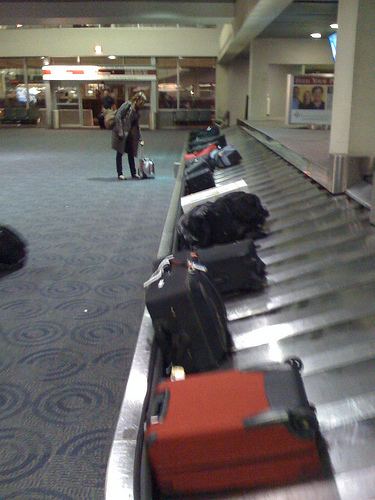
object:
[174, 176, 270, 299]
bunch of luggage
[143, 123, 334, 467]
row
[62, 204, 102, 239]
carpet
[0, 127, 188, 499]
floor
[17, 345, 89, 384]
circular design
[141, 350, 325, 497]
bag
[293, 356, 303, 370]
wheels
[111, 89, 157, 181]
woman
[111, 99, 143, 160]
coat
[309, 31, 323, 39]
light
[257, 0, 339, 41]
ceiling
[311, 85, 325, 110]
people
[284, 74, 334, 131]
advertisement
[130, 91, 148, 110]
hair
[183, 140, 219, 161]
luggage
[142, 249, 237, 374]
luggage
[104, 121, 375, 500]
baggage carousel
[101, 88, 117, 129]
man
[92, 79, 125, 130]
entryway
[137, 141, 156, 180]
luggage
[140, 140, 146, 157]
handle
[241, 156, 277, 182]
belt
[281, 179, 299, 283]
metal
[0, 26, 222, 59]
wall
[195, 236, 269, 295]
suitcase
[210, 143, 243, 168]
suitcase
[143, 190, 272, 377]
three suitcases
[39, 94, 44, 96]
shops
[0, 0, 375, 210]
airport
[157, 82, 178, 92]
sign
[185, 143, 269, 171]
distance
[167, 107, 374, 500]
baggage claim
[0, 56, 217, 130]
restaurant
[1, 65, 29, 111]
huge windows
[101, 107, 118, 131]
luggage